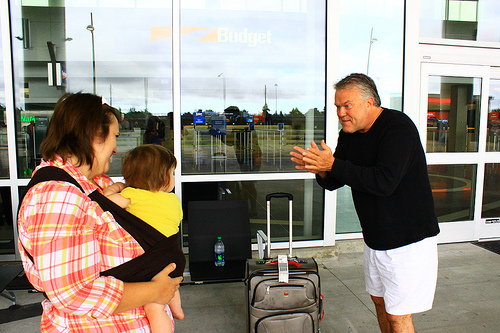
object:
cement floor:
[4, 238, 499, 331]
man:
[289, 72, 441, 331]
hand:
[301, 139, 335, 172]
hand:
[288, 140, 319, 169]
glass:
[180, 0, 325, 175]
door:
[10, 0, 341, 254]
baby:
[102, 143, 187, 332]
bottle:
[213, 236, 225, 267]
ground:
[448, 125, 466, 144]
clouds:
[81, 16, 320, 66]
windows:
[171, 0, 326, 183]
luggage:
[243, 192, 325, 332]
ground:
[327, 301, 357, 330]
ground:
[447, 259, 499, 310]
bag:
[187, 182, 252, 280]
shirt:
[314, 106, 440, 250]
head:
[39, 91, 123, 179]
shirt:
[118, 186, 184, 238]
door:
[420, 62, 499, 245]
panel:
[427, 74, 482, 154]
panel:
[428, 164, 477, 222]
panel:
[485, 78, 499, 152]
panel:
[479, 163, 500, 219]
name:
[215, 26, 273, 47]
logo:
[149, 26, 216, 42]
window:
[179, 0, 325, 175]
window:
[0, 0, 181, 187]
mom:
[15, 89, 182, 333]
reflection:
[206, 105, 262, 216]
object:
[187, 199, 253, 281]